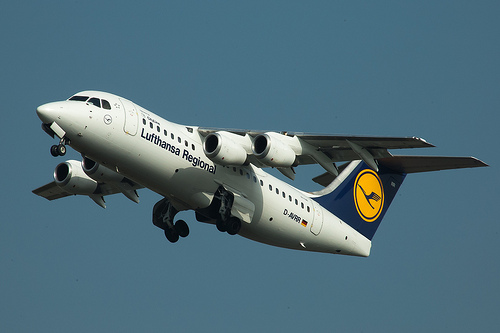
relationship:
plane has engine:
[30, 59, 422, 329] [198, 119, 255, 177]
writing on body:
[150, 138, 207, 161] [109, 59, 286, 228]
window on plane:
[167, 121, 191, 135] [30, 59, 422, 329]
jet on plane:
[228, 98, 315, 181] [30, 59, 422, 329]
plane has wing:
[30, 59, 422, 329] [299, 102, 424, 164]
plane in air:
[30, 59, 422, 329] [281, 45, 360, 109]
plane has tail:
[30, 59, 422, 329] [324, 138, 435, 240]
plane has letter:
[30, 59, 422, 329] [150, 104, 222, 168]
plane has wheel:
[30, 59, 422, 329] [155, 215, 206, 252]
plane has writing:
[30, 59, 422, 329] [150, 138, 207, 161]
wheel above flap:
[155, 215, 206, 252] [289, 117, 410, 180]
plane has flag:
[30, 59, 422, 329] [346, 172, 401, 221]